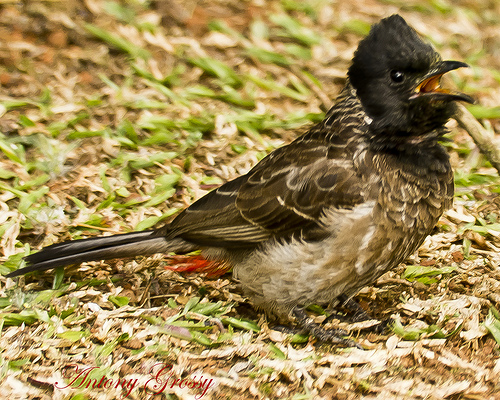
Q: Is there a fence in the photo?
A: No, there are no fences.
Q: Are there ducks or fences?
A: No, there are no fences or ducks.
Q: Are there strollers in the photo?
A: No, there are no strollers.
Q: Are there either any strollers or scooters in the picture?
A: No, there are no strollers or scooters.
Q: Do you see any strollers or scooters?
A: No, there are no strollers or scooters.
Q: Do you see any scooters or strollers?
A: No, there are no strollers or scooters.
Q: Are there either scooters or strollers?
A: No, there are no strollers or scooters.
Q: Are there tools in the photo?
A: No, there are no tools.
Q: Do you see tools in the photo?
A: No, there are no tools.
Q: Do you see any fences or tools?
A: No, there are no tools or fences.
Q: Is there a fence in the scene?
A: No, there are no fences.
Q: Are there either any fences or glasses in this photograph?
A: No, there are no fences or glasses.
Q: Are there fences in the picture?
A: No, there are no fences.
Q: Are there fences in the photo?
A: No, there are no fences.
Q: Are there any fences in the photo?
A: No, there are no fences.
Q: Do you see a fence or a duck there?
A: No, there are no ducks or fences.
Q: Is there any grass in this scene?
A: Yes, there is grass.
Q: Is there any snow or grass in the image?
A: Yes, there is grass.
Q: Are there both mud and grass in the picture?
A: No, there is grass but no mud.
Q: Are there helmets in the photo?
A: No, there are no helmets.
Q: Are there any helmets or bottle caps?
A: No, there are no helmets or bottle caps.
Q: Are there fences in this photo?
A: No, there are no fences.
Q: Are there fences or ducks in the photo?
A: No, there are no fences or ducks.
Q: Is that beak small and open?
A: Yes, the beak is small and open.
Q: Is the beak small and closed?
A: No, the beak is small but open.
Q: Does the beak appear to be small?
A: Yes, the beak is small.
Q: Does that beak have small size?
A: Yes, the beak is small.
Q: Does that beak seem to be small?
A: Yes, the beak is small.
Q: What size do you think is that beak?
A: The beak is small.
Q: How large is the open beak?
A: The beak is small.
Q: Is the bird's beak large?
A: No, the beak is small.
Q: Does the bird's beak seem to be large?
A: No, the beak is small.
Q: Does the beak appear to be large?
A: No, the beak is small.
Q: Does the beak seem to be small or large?
A: The beak is small.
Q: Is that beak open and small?
A: Yes, the beak is open and small.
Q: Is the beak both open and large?
A: No, the beak is open but small.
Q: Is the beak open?
A: Yes, the beak is open.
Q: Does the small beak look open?
A: Yes, the beak is open.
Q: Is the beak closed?
A: No, the beak is open.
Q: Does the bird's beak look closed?
A: No, the beak is open.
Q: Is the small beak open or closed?
A: The beak is open.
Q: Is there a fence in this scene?
A: No, there are no fences.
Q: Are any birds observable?
A: Yes, there is a bird.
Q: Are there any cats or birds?
A: Yes, there is a bird.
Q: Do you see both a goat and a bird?
A: No, there is a bird but no goats.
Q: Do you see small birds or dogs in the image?
A: Yes, there is a small bird.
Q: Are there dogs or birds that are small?
A: Yes, the bird is small.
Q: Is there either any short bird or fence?
A: Yes, there is a short bird.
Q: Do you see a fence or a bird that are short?
A: Yes, the bird is short.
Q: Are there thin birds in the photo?
A: Yes, there is a thin bird.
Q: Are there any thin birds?
A: Yes, there is a thin bird.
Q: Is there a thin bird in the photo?
A: Yes, there is a thin bird.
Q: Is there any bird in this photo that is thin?
A: Yes, there is a bird that is thin.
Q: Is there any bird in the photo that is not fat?
A: Yes, there is a thin bird.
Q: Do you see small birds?
A: Yes, there is a small bird.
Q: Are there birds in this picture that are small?
A: Yes, there is a bird that is small.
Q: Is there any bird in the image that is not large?
A: Yes, there is a small bird.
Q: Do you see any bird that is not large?
A: Yes, there is a small bird.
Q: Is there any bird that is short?
A: Yes, there is a short bird.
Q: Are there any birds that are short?
A: Yes, there is a bird that is short.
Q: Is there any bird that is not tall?
A: Yes, there is a short bird.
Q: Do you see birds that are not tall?
A: Yes, there is a short bird.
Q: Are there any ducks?
A: No, there are no ducks.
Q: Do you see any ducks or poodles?
A: No, there are no ducks or poodles.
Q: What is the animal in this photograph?
A: The animal is a bird.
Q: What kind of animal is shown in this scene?
A: The animal is a bird.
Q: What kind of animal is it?
A: The animal is a bird.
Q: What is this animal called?
A: This is a bird.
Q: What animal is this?
A: This is a bird.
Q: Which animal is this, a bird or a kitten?
A: This is a bird.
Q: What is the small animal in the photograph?
A: The animal is a bird.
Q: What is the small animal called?
A: The animal is a bird.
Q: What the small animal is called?
A: The animal is a bird.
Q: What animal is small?
A: The animal is a bird.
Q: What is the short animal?
A: The animal is a bird.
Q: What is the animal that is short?
A: The animal is a bird.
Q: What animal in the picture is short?
A: The animal is a bird.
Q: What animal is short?
A: The animal is a bird.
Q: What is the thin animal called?
A: The animal is a bird.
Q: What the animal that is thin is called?
A: The animal is a bird.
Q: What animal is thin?
A: The animal is a bird.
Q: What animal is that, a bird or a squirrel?
A: That is a bird.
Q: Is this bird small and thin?
A: Yes, the bird is small and thin.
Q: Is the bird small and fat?
A: No, the bird is small but thin.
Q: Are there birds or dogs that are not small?
A: No, there is a bird but it is small.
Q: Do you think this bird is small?
A: Yes, the bird is small.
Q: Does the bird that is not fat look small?
A: Yes, the bird is small.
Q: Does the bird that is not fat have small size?
A: Yes, the bird is small.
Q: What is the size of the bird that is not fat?
A: The bird is small.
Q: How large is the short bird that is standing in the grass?
A: The bird is small.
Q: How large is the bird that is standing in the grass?
A: The bird is small.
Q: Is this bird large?
A: No, the bird is small.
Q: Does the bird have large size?
A: No, the bird is small.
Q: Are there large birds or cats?
A: No, there is a bird but it is small.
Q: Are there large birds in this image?
A: No, there is a bird but it is small.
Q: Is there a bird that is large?
A: No, there is a bird but it is small.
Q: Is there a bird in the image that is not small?
A: No, there is a bird but it is small.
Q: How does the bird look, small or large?
A: The bird is small.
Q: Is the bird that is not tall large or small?
A: The bird is small.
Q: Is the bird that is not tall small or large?
A: The bird is small.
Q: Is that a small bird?
A: Yes, that is a small bird.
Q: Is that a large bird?
A: No, that is a small bird.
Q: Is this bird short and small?
A: Yes, the bird is short and small.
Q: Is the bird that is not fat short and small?
A: Yes, the bird is short and small.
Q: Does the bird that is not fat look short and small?
A: Yes, the bird is short and small.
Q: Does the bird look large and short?
A: No, the bird is short but small.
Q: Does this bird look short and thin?
A: Yes, the bird is short and thin.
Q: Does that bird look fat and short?
A: No, the bird is short but thin.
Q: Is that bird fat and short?
A: No, the bird is short but thin.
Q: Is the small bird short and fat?
A: No, the bird is short but thin.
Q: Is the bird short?
A: Yes, the bird is short.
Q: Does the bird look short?
A: Yes, the bird is short.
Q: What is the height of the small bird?
A: The bird is short.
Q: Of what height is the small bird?
A: The bird is short.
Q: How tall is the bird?
A: The bird is short.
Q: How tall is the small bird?
A: The bird is short.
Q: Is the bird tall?
A: No, the bird is short.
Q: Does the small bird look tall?
A: No, the bird is short.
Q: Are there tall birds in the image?
A: No, there is a bird but it is short.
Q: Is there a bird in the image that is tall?
A: No, there is a bird but it is short.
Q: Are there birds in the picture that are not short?
A: No, there is a bird but it is short.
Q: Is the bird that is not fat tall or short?
A: The bird is short.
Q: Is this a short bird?
A: Yes, this is a short bird.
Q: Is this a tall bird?
A: No, this is a short bird.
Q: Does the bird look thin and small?
A: Yes, the bird is thin and small.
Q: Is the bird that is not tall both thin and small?
A: Yes, the bird is thin and small.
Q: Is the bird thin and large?
A: No, the bird is thin but small.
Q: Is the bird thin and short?
A: Yes, the bird is thin and short.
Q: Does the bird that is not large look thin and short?
A: Yes, the bird is thin and short.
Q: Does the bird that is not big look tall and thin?
A: No, the bird is thin but short.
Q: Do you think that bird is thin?
A: Yes, the bird is thin.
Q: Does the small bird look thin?
A: Yes, the bird is thin.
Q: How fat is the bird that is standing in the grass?
A: The bird is thin.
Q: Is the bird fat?
A: No, the bird is thin.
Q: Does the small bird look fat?
A: No, the bird is thin.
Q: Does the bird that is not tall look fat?
A: No, the bird is thin.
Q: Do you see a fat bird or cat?
A: No, there is a bird but it is thin.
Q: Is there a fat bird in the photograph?
A: No, there is a bird but it is thin.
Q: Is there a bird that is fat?
A: No, there is a bird but it is thin.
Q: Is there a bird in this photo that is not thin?
A: No, there is a bird but it is thin.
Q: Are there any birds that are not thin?
A: No, there is a bird but it is thin.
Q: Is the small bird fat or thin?
A: The bird is thin.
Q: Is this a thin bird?
A: Yes, this is a thin bird.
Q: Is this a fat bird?
A: No, this is a thin bird.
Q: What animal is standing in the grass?
A: The bird is standing in the grass.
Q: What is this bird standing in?
A: The bird is standing in the grass.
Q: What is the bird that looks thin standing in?
A: The bird is standing in the grass.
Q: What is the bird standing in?
A: The bird is standing in the grass.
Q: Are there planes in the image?
A: No, there are no planes.